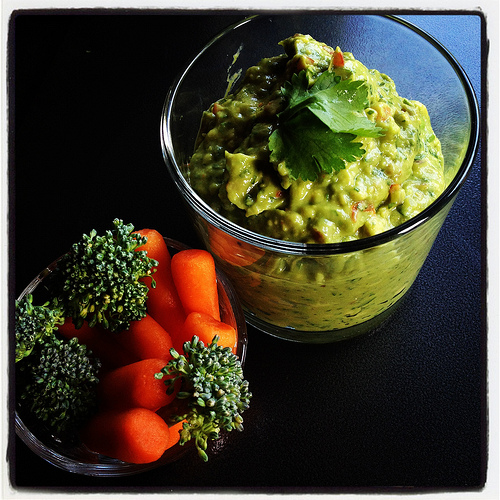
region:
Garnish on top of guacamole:
[263, 65, 386, 185]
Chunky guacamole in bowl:
[189, 32, 445, 241]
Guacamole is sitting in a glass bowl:
[155, 6, 481, 349]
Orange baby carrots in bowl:
[65, 227, 240, 464]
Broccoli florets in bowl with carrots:
[47, 216, 161, 333]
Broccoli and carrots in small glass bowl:
[12, 222, 269, 479]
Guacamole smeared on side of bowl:
[216, 49, 252, 88]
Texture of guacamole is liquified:
[217, 253, 459, 332]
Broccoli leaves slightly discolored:
[76, 294, 116, 322]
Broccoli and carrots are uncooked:
[10, 220, 256, 462]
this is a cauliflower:
[157, 338, 258, 459]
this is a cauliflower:
[69, 215, 139, 330]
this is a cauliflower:
[9, 285, 61, 362]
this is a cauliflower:
[27, 335, 110, 430]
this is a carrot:
[94, 410, 177, 463]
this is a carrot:
[105, 361, 176, 406]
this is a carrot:
[105, 308, 177, 369]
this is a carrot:
[177, 308, 247, 379]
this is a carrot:
[167, 238, 242, 343]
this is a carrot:
[121, 213, 186, 327]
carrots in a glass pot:
[16, 231, 253, 481]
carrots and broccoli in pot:
[15, 216, 260, 474]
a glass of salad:
[151, 13, 472, 348]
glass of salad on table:
[141, 11, 471, 355]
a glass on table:
[15, 233, 256, 480]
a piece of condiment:
[265, 73, 370, 184]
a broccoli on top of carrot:
[40, 223, 162, 329]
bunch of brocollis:
[19, 228, 257, 458]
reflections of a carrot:
[207, 225, 269, 275]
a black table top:
[305, 365, 482, 494]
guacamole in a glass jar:
[155, 10, 483, 335]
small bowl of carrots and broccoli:
[11, 223, 251, 478]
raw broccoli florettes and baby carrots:
[15, 218, 251, 473]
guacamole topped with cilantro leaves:
[181, 31, 415, 236]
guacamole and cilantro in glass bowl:
[172, 24, 444, 331]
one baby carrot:
[166, 246, 227, 326]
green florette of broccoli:
[155, 330, 257, 460]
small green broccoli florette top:
[50, 214, 156, 331]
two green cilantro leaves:
[266, 68, 386, 183]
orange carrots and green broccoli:
[115, 339, 251, 461]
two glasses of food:
[18, 15, 483, 483]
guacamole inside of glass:
[190, 31, 450, 337]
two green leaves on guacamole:
[270, 67, 380, 175]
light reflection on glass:
[157, 99, 179, 161]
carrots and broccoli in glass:
[16, 221, 247, 476]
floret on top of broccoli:
[63, 218, 150, 322]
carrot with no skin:
[170, 247, 220, 319]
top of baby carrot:
[130, 411, 169, 463]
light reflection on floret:
[193, 333, 251, 415]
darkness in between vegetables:
[60, 376, 127, 455]